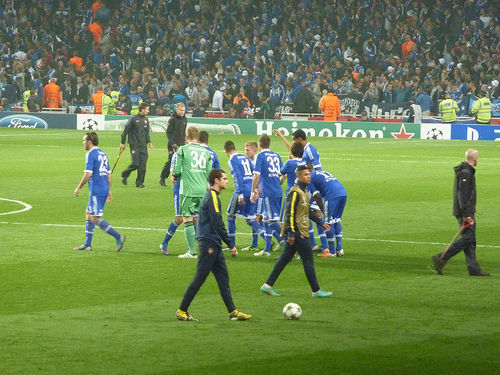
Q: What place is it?
A: It is a field.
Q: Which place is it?
A: It is a field.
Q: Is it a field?
A: Yes, it is a field.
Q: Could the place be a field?
A: Yes, it is a field.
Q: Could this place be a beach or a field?
A: It is a field.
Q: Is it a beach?
A: No, it is a field.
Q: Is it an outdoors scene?
A: Yes, it is outdoors.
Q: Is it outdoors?
A: Yes, it is outdoors.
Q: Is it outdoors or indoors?
A: It is outdoors.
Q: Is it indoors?
A: No, it is outdoors.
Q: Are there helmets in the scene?
A: No, there are no helmets.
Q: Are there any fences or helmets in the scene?
A: No, there are no helmets or fences.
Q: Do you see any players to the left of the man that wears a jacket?
A: Yes, there are players to the left of the man.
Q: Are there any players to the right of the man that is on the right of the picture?
A: No, the players are to the left of the man.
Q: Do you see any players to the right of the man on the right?
A: No, the players are to the left of the man.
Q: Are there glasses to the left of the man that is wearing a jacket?
A: No, there are players to the left of the man.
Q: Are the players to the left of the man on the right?
A: Yes, the players are to the left of the man.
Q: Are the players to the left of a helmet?
A: No, the players are to the left of the man.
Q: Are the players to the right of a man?
A: No, the players are to the left of a man.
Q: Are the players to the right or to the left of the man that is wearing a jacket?
A: The players are to the left of the man.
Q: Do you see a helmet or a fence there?
A: No, there are no helmets or fences.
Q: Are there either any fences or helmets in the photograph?
A: No, there are no helmets or fences.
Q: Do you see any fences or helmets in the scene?
A: No, there are no helmets or fences.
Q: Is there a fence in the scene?
A: No, there are no fences.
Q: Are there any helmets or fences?
A: No, there are no fences or helmets.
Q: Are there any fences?
A: No, there are no fences.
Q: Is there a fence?
A: No, there are no fences.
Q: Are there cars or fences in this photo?
A: No, there are no fences or cars.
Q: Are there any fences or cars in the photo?
A: No, there are no fences or cars.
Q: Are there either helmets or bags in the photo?
A: No, there are no helmets or bags.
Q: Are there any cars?
A: No, there are no cars.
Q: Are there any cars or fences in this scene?
A: No, there are no cars or fences.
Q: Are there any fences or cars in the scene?
A: No, there are no cars or fences.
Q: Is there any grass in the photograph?
A: Yes, there is grass.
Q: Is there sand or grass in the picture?
A: Yes, there is grass.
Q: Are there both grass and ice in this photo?
A: No, there is grass but no ice.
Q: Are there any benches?
A: No, there are no benches.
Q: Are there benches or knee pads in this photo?
A: No, there are no benches or knee pads.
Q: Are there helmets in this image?
A: No, there are no helmets.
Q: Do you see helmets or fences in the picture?
A: No, there are no helmets or fences.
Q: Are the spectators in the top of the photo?
A: Yes, the spectators are in the top of the image.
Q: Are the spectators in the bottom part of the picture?
A: No, the spectators are in the top of the image.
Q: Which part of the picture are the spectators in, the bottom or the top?
A: The spectators are in the top of the image.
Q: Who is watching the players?
A: The spectators are watching the players.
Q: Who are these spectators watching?
A: The spectators are watching the players.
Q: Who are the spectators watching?
A: The spectators are watching the players.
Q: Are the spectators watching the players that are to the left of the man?
A: Yes, the spectators are watching the players.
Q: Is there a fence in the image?
A: No, there are no fences.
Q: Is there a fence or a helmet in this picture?
A: No, there are no fences or helmets.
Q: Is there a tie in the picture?
A: No, there are no ties.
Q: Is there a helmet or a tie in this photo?
A: No, there are no ties or helmets.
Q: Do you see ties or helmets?
A: No, there are no ties or helmets.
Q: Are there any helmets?
A: No, there are no helmets.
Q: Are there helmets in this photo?
A: No, there are no helmets.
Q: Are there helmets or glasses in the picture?
A: No, there are no helmets or glasses.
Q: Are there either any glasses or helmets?
A: No, there are no helmets or glasses.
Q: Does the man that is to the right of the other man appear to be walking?
A: Yes, the man is walking.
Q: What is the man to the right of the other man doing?
A: The man is walking.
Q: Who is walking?
A: The man is walking.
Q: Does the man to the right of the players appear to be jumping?
A: No, the man is walking.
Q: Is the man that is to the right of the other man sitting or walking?
A: The man is walking.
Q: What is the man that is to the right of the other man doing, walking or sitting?
A: The man is walking.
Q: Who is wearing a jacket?
A: The man is wearing a jacket.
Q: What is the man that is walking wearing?
A: The man is wearing a jacket.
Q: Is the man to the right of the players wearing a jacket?
A: Yes, the man is wearing a jacket.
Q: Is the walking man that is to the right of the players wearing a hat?
A: No, the man is wearing a jacket.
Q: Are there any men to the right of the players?
A: Yes, there is a man to the right of the players.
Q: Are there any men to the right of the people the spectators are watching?
A: Yes, there is a man to the right of the players.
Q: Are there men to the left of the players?
A: No, the man is to the right of the players.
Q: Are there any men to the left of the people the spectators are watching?
A: No, the man is to the right of the players.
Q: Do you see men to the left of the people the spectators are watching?
A: No, the man is to the right of the players.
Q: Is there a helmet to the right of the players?
A: No, there is a man to the right of the players.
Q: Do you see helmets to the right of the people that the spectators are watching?
A: No, there is a man to the right of the players.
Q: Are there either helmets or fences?
A: No, there are no helmets or fences.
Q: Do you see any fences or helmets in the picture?
A: No, there are no helmets or fences.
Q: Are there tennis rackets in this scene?
A: No, there are no tennis rackets.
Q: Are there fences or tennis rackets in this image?
A: No, there are no tennis rackets or fences.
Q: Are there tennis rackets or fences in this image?
A: No, there are no tennis rackets or fences.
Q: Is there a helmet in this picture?
A: No, there are no helmets.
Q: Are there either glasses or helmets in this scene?
A: No, there are no helmets or glasses.